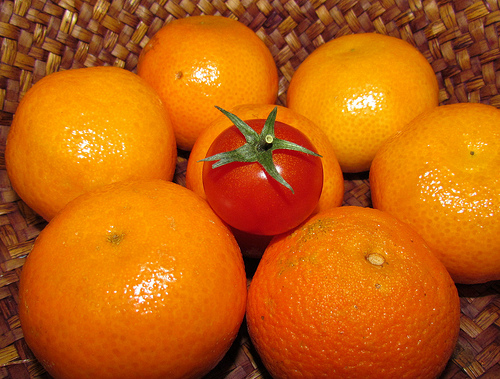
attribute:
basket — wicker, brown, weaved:
[25, 7, 168, 48]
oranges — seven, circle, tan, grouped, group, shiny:
[19, 45, 274, 149]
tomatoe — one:
[196, 107, 335, 236]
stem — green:
[241, 126, 292, 168]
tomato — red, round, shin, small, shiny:
[195, 122, 355, 252]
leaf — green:
[230, 109, 316, 185]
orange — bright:
[285, 34, 430, 165]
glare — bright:
[340, 84, 385, 122]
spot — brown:
[293, 115, 323, 146]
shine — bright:
[63, 110, 156, 179]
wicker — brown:
[49, 2, 498, 50]